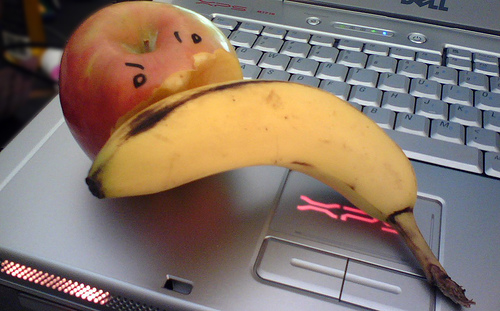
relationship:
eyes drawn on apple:
[185, 29, 202, 44] [61, 3, 237, 174]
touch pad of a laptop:
[252, 164, 450, 309] [5, 0, 475, 298]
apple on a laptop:
[58, 0, 244, 163] [5, 0, 475, 298]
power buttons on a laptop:
[304, 11, 324, 30] [5, 0, 475, 298]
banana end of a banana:
[79, 167, 112, 201] [87, 77, 475, 309]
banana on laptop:
[55, 74, 483, 293] [0, 0, 500, 310]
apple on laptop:
[58, 3, 258, 148] [0, 0, 500, 310]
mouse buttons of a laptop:
[339, 256, 437, 310] [5, 0, 475, 298]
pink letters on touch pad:
[300, 192, 400, 240] [252, 164, 450, 309]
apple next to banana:
[58, 0, 244, 163] [87, 77, 475, 309]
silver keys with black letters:
[207, 12, 496, 173] [260, 26, 481, 101]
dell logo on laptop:
[397, 0, 452, 18] [5, 0, 475, 298]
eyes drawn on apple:
[121, 29, 203, 89] [58, 0, 242, 161]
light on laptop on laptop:
[369, 25, 379, 33] [5, 0, 475, 298]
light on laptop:
[379, 29, 389, 37] [5, 0, 475, 298]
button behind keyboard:
[406, 30, 429, 46] [208, 11, 498, 181]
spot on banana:
[228, 96, 238, 105] [87, 77, 475, 309]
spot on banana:
[263, 126, 271, 134] [87, 77, 475, 309]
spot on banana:
[280, 113, 290, 123] [87, 77, 475, 309]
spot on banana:
[328, 108, 338, 117] [87, 77, 475, 309]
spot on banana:
[289, 157, 319, 169] [87, 77, 475, 309]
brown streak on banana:
[128, 76, 293, 143] [87, 77, 475, 309]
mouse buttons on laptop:
[249, 235, 450, 310] [5, 0, 475, 298]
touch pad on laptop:
[257, 164, 449, 309] [5, 0, 475, 298]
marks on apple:
[124, 29, 202, 87] [58, 0, 242, 161]